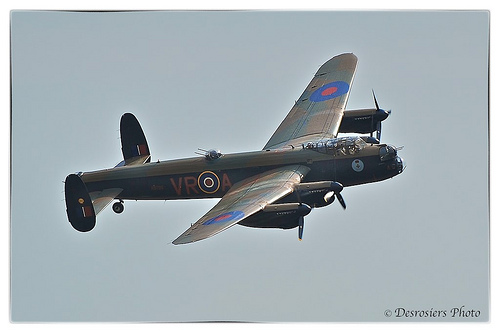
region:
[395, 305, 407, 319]
black print style letter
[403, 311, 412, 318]
black print style letter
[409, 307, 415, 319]
black print style letter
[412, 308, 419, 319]
black print style letter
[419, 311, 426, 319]
black print style letter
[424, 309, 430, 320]
black print style letter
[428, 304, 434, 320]
black print style letter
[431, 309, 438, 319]
black print style letter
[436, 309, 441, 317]
black print style letter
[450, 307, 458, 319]
black print style letter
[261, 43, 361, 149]
wing of a plane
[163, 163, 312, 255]
wing of a plane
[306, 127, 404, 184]
cockpit of a plane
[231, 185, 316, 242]
engine of a plane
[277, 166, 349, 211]
engine of a plane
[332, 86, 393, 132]
engine of a plane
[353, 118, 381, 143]
engine of a plane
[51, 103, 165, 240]
tail of a plane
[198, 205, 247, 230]
logo on a plane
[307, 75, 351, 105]
logo on a plane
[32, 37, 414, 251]
jet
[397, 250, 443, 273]
white clouds in blue sky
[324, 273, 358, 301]
white clouds in blue sky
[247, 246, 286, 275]
white clouds in blue sky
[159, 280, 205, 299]
white clouds in blue sky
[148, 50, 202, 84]
white clouds in blue sky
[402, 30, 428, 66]
white clouds in blue sky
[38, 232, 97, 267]
white clouds in blue sky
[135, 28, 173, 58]
white clouds in blue sky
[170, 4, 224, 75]
white clouds in blue sky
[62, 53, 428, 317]
an airplane in the air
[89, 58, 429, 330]
a plane in the air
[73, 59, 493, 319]
an airplane in the sky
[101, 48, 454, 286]
a plane inthe sky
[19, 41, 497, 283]
an airplane that is flying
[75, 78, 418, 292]
a plane that is flying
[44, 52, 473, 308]
a small airplane in the air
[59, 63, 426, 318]
a small plane in the air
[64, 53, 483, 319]
a small airplane in the sky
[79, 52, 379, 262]
a small plane in the sky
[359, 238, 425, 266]
white clouds in blue sky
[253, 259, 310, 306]
white clouds in blue sky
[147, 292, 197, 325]
white clouds in blue sky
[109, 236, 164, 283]
white clouds in blue sky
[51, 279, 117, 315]
white clouds in blue sky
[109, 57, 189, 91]
white clouds in blue sky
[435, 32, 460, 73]
white clouds in blue sky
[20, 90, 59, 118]
white clouds in blue sky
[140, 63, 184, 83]
white clouds in blue sky